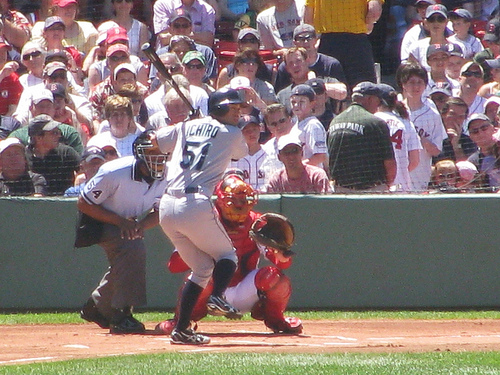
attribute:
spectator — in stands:
[21, 114, 88, 201]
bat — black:
[141, 41, 199, 117]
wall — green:
[2, 193, 500, 318]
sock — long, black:
[170, 278, 204, 335]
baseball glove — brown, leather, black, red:
[247, 212, 296, 259]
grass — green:
[0, 303, 499, 328]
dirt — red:
[0, 317, 497, 362]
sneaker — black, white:
[169, 326, 212, 346]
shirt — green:
[325, 107, 395, 190]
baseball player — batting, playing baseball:
[149, 85, 249, 346]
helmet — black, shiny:
[204, 87, 249, 121]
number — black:
[176, 138, 213, 174]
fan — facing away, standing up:
[324, 82, 393, 197]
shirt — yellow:
[302, 1, 385, 35]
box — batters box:
[154, 331, 276, 352]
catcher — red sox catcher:
[152, 172, 303, 336]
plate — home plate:
[153, 329, 173, 345]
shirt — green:
[6, 117, 84, 149]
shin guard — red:
[252, 263, 293, 322]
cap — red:
[104, 26, 132, 48]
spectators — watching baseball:
[0, 1, 499, 198]